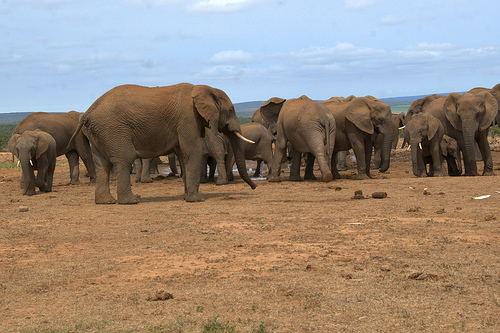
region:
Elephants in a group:
[84, 78, 434, 170]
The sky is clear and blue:
[134, 31, 455, 97]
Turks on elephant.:
[241, 136, 268, 150]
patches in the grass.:
[141, 272, 198, 311]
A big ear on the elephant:
[184, 79, 213, 132]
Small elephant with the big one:
[8, 128, 65, 190]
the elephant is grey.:
[270, 88, 360, 193]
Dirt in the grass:
[67, 217, 237, 277]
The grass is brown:
[62, 222, 289, 293]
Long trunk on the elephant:
[231, 130, 260, 184]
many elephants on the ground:
[30, 47, 482, 252]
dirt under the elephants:
[213, 198, 308, 260]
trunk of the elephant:
[226, 140, 272, 192]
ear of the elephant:
[183, 81, 228, 133]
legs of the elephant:
[95, 143, 220, 230]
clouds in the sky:
[290, 19, 370, 79]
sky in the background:
[211, 11, 340, 79]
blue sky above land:
[252, 7, 319, 42]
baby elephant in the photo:
[2, 114, 72, 198]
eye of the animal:
[221, 100, 246, 120]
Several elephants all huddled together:
[2, 77, 487, 211]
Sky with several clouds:
[0, 0, 496, 90]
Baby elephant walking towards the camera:
[2, 125, 62, 191]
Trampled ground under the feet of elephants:
[0, 145, 498, 330]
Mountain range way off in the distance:
[0, 73, 497, 105]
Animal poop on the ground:
[348, 187, 393, 209]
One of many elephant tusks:
[227, 120, 257, 148]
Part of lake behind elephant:
[242, 165, 267, 182]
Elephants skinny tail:
[308, 108, 343, 158]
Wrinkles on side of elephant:
[102, 92, 186, 152]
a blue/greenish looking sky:
[11, 6, 496, 115]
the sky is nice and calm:
[6, 6, 498, 108]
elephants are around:
[0, 81, 497, 198]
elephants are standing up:
[11, 83, 498, 191]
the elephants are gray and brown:
[16, 82, 498, 187]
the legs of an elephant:
[96, 163, 146, 207]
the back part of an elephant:
[72, 97, 142, 198]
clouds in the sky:
[210, 51, 478, 76]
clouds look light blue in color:
[302, 43, 427, 82]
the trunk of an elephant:
[227, 134, 261, 187]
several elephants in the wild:
[4, 50, 497, 247]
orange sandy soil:
[4, 208, 465, 323]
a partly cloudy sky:
[0, 1, 499, 71]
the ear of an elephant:
[186, 83, 218, 138]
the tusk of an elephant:
[233, 129, 254, 144]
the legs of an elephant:
[92, 158, 206, 210]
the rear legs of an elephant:
[87, 155, 141, 205]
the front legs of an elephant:
[174, 155, 209, 205]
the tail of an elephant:
[62, 113, 79, 153]